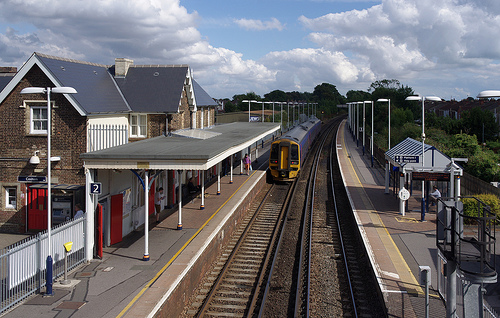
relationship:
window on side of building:
[24, 97, 53, 131] [0, 49, 132, 239]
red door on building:
[20, 186, 57, 235] [6, 52, 88, 246]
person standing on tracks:
[235, 146, 260, 180] [209, 199, 292, 301]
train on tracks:
[253, 108, 338, 192] [209, 199, 292, 301]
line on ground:
[108, 158, 272, 315] [86, 174, 285, 285]